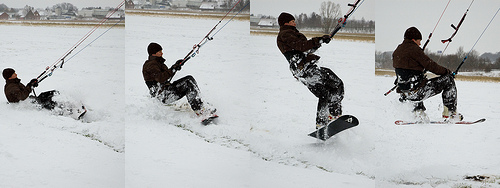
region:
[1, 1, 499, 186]
a collage of a kite boarder in the snow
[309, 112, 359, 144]
a snowboard off the ground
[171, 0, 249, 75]
the kite control cables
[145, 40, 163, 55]
a black knit cap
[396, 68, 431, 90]
the kite cable harness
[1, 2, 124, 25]
residential homes in the distance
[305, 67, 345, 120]
the skier is wearing black ski pants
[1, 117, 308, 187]
deep wet slushy snow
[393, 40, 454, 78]
the skier is wearing a brown ski jacket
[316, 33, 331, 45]
the kite boarder has black gloves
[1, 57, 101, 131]
The man is lying in the snow.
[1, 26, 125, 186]
The snow is white.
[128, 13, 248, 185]
The snow is white.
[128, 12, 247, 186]
The man's knees are bent.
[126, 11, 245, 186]
The man is wearing a cap.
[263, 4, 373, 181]
The man is on a snowboard.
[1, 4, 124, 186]
The man is holding onto cords.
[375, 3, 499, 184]
The man's knees are bent.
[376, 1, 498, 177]
The man is in a sitting position.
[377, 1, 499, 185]
The snow is white.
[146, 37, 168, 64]
a man wearing a black hat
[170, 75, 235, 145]
a man on a snow board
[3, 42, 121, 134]
a man on the ground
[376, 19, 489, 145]
a man off the ground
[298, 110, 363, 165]
a black snow board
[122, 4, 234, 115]
a man holding on to ropes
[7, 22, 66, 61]
the ground covered with snow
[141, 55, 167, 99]
a man wearing a brown jacket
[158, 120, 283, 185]
tracks in the snow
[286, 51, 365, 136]
a man wearing black pants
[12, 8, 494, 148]
a man doing a trick on snow board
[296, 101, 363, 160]
a black snowboard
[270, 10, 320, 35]
black hat on head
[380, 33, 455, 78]
a dark brown jacket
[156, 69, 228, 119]
black snow pants on legs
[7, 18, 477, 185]
lots of snow on the ground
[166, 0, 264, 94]
wires reaching into the sky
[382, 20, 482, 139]
man looks like hes sitting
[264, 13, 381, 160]
a man on a snowboard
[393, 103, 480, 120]
boots on his feet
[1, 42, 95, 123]
man with back in snow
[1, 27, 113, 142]
man with snow on him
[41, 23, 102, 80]
item that man is holding onto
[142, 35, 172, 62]
hat on man's head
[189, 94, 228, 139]
snowboard in the snow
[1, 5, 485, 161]
four different photos of the same guy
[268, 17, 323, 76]
warm gear on the man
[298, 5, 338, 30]
trees in the distance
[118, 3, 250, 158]
second photo from the left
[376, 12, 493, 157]
man in the air